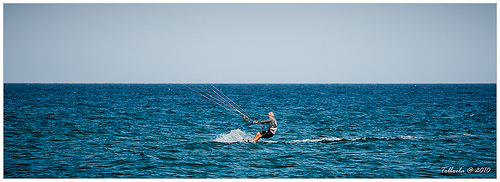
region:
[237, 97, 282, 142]
this is a person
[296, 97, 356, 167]
this is a body of water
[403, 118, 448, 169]
this is a body of water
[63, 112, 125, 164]
this is a body of water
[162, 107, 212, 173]
this is a body of water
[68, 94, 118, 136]
this is a body of water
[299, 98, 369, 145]
this is a body of water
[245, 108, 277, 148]
Man parasailing in ocean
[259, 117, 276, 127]
Gray shirt on man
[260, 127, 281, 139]
Black shorts on man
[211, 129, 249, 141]
White foamy water in front of man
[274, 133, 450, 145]
Long rippled wake behind man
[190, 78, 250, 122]
Strings attached to sail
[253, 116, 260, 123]
Man's hands gripping handle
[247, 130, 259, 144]
Man's bare legs on water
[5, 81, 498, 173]
Deep blue expanse of ocean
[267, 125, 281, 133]
White part of shirt on man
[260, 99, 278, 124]
head of a person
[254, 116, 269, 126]
arm of a person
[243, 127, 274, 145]
leg of a person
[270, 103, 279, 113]
hair of a person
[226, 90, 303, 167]
person on a water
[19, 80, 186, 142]
clear body of water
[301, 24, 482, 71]
clear blue sky with no clouds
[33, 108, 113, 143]
body of clear blue water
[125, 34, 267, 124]
strings in the sky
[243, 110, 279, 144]
A man surfing on the ocean.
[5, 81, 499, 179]
Deep blue water of the ocean.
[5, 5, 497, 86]
A clear, cloudless blue sky.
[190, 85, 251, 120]
Rope connected to a kite.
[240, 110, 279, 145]
A man leaning as he surfs.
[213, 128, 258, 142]
Water splashing off the bottom of a surf board.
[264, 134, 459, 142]
Water ripples off the back of a surf board.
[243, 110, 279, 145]
A man in gray and black surfing.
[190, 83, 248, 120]
Ropes for kite surfing.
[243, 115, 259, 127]
Black, kite surfing handle.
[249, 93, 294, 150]
parasurfer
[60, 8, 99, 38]
white clouds in blue sky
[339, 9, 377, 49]
white clouds in blue sky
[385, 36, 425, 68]
white clouds in blue sky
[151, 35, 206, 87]
white clouds in blue sky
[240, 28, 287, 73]
white clouds in blue sky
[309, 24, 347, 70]
white clouds in blue sky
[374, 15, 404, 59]
white clouds in blue sky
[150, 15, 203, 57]
white clouds in blue sky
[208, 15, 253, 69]
white clouds in blue sky